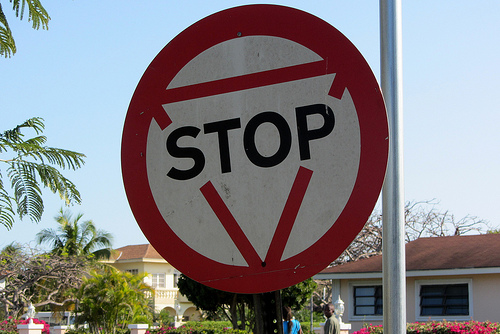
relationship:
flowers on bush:
[447, 321, 498, 332] [355, 318, 498, 331]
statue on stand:
[23, 301, 43, 321] [17, 322, 42, 332]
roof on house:
[317, 233, 499, 274] [306, 230, 499, 331]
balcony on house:
[139, 279, 178, 312] [306, 230, 499, 331]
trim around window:
[413, 277, 474, 322] [404, 277, 491, 323]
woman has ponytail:
[275, 304, 304, 331] [287, 321, 295, 331]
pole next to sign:
[376, 0, 411, 331] [116, 1, 393, 298]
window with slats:
[418, 283, 470, 315] [418, 283, 468, 315]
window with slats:
[418, 283, 470, 315] [354, 285, 384, 314]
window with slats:
[418, 283, 470, 315] [151, 272, 165, 288]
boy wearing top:
[322, 303, 339, 334] [323, 317, 340, 331]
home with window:
[307, 227, 497, 325] [345, 280, 385, 321]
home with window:
[307, 227, 497, 325] [410, 273, 472, 318]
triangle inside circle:
[147, 53, 347, 272] [119, 1, 392, 303]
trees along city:
[0, 220, 157, 330] [16, 66, 478, 334]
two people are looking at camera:
[282, 284, 368, 334] [254, 216, 438, 334]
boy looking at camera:
[320, 301, 337, 331] [4, 66, 484, 334]